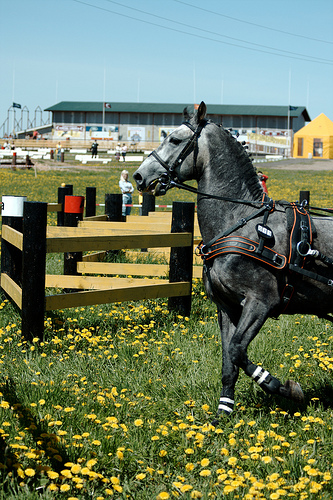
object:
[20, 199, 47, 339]
fence post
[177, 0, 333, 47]
wires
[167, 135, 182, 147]
eye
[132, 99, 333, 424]
horse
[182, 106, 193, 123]
ear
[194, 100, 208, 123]
ear